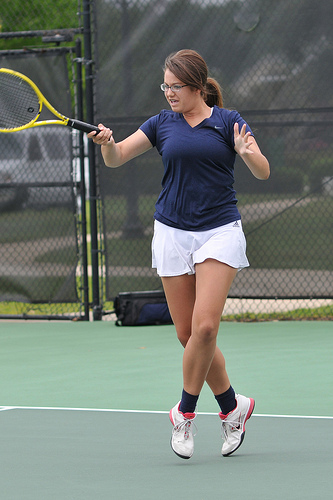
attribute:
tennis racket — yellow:
[0, 64, 109, 142]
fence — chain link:
[1, 1, 330, 498]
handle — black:
[60, 106, 102, 137]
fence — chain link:
[207, 18, 327, 159]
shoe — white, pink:
[166, 406, 194, 458]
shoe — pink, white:
[219, 389, 255, 443]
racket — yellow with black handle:
[0, 63, 117, 144]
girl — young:
[87, 49, 269, 459]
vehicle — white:
[11, 116, 111, 221]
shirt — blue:
[136, 99, 251, 230]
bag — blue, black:
[115, 290, 172, 327]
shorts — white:
[152, 217, 249, 276]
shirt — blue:
[157, 106, 251, 217]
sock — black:
[212, 384, 236, 417]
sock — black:
[176, 388, 199, 414]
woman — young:
[85, 49, 270, 458]